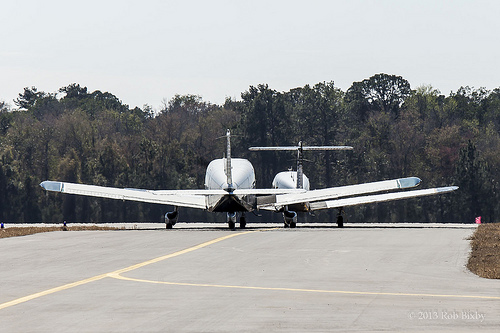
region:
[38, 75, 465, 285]
two planes next to each other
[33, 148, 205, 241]
wing of the plane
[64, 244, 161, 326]
yellow lines on ground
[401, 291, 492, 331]
words on bottom right corner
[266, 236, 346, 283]
gray ground in photo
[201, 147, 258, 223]
tail of the plane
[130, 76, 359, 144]
trees in the distance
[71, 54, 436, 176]
many trees in front of planes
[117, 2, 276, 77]
sky above the trees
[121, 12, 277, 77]
sky with no clouds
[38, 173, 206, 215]
the wing of a plane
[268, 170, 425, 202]
the wing of a plane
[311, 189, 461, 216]
the wing of a plane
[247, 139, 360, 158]
the tail wing of a plane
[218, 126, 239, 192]
the tail of a plane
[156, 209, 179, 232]
the landing gear of a plane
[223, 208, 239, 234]
the landing gear of a plane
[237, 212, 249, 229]
the landing gear of a plane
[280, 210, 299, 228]
the landing gear of a plane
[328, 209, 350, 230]
the landing gear of a plane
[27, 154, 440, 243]
the plane on the runway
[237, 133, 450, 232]
the plane on the runway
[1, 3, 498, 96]
the sky is blue and clear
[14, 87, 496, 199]
the trees behind the planes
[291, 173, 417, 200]
wing of the plane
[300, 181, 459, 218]
the wing of the plane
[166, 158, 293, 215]
tail of the plane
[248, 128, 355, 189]
the tail of the plane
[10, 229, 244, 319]
the yellow line on the runway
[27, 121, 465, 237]
Two airplanes on the pavement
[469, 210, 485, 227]
Cones on the ground.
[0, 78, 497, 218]
Trees at the end of the pavement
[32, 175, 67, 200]
Blue tip on the wind.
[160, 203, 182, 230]
wheel on the plane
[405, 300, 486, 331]
White lettering bottom right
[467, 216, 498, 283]
grass covering the ground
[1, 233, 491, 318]
Yellow lines on the pavement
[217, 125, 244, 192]
Tail wing on the plane.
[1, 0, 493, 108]
Blue sky in the background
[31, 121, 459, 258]
A white plane with blue tips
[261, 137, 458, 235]
A plane in front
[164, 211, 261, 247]
Wheels on a white plane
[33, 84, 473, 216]
A long row of trees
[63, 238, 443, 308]
A pavement runway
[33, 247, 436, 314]
Yellow lines on runway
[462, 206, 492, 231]
A red object on right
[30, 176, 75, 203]
Blue tip of plane wing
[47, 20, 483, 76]
A blue sky in front of planes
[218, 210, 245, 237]
Front wheel of plane